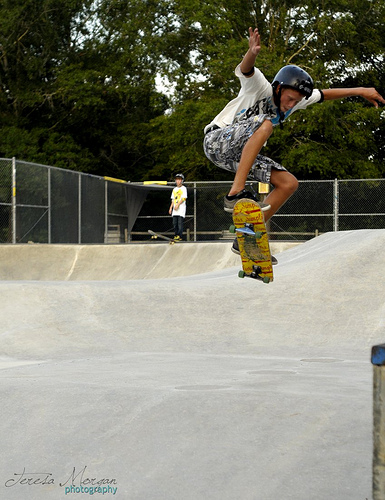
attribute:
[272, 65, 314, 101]
helmet — black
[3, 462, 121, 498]
name — responsible, calibri, black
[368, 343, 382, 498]
rail — stair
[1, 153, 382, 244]
fence — chainlink, link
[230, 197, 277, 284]
skateboard — red, yellow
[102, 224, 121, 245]
can — plastic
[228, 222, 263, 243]
wheels — greenish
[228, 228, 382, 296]
ramp — concrete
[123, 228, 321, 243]
bench — wooden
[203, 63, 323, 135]
shirt — white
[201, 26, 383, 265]
boy — skateboarding, tricking, standing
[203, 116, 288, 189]
shorts — black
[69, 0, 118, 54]
sky — blue